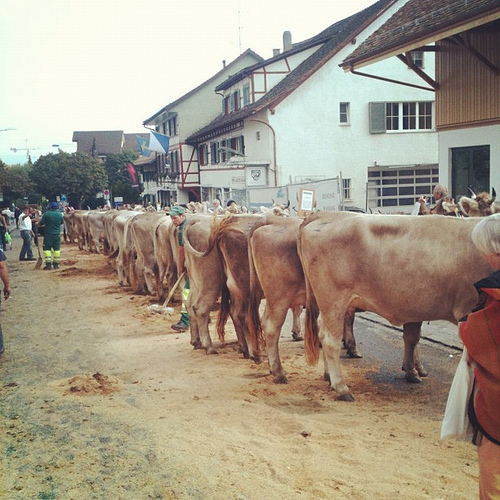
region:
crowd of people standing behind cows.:
[0, 201, 95, 298]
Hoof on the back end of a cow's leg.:
[313, 367, 358, 407]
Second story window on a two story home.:
[335, 94, 350, 128]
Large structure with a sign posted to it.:
[286, 169, 351, 219]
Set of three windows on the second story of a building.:
[366, 97, 443, 139]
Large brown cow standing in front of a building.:
[295, 211, 498, 393]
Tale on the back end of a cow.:
[180, 216, 228, 262]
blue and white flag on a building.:
[141, 125, 188, 156]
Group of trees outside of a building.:
[0, 130, 145, 207]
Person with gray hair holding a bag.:
[430, 206, 495, 496]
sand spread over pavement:
[1, 204, 479, 498]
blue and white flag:
[146, 127, 170, 153]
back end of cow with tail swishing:
[177, 211, 239, 358]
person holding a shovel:
[33, 200, 64, 272]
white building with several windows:
[141, 1, 436, 214]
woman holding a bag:
[434, 214, 499, 498]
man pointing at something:
[16, 204, 37, 261]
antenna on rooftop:
[235, 0, 243, 55]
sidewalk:
[352, 308, 463, 349]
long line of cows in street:
[61, 208, 498, 409]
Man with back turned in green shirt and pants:
[28, 192, 107, 298]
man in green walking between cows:
[142, 188, 254, 399]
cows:
[61, 202, 498, 423]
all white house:
[146, 15, 439, 225]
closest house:
[354, 16, 496, 243]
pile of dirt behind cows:
[33, 356, 140, 441]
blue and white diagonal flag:
[121, 108, 175, 176]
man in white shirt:
[16, 202, 45, 274]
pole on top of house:
[224, 7, 269, 74]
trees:
[1, 153, 148, 237]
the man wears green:
[37, 197, 77, 271]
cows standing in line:
[104, 210, 469, 370]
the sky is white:
[18, 97, 143, 124]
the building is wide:
[137, 96, 442, 198]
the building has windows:
[367, 93, 442, 143]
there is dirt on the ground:
[177, 404, 403, 488]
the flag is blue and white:
[143, 127, 173, 154]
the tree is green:
[8, 147, 122, 196]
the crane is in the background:
[11, 135, 51, 160]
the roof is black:
[72, 127, 142, 153]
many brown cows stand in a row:
[24, 173, 499, 399]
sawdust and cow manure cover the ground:
[3, 305, 444, 496]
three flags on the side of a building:
[96, 115, 189, 192]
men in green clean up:
[1, 195, 196, 332]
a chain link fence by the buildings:
[209, 162, 348, 227]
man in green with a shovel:
[15, 185, 70, 275]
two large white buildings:
[141, 25, 376, 202]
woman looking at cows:
[435, 195, 495, 496]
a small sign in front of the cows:
[262, 150, 327, 216]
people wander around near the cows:
[0, 176, 96, 319]